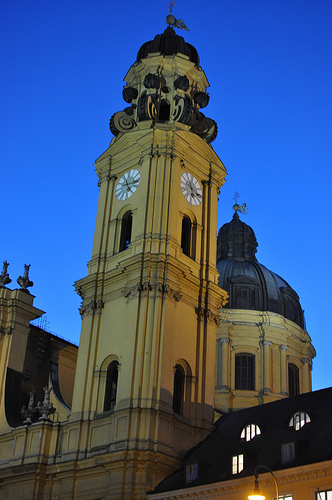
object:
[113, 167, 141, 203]
clock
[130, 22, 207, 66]
domed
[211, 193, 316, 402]
tower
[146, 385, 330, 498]
portion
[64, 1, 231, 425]
tower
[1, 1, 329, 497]
building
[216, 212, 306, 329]
roof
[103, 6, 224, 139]
steel guide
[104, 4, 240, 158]
tower top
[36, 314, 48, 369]
ladder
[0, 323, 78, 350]
roof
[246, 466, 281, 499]
light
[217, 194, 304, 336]
glass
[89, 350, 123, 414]
window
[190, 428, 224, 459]
black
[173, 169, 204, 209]
clock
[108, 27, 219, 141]
roof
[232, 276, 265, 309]
room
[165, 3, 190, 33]
weather meter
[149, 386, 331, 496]
roof